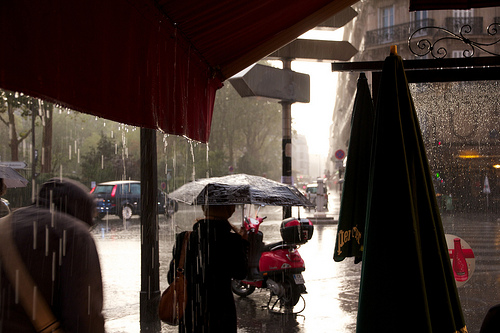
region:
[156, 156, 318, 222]
person holding an umbrella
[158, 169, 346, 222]
the umbrella is black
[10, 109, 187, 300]
it is raining in scene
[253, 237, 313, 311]
the motorcycle is red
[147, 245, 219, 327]
person carrying a purse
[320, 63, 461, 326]
the umbrellas are closed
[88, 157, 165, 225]
car's tail lights are on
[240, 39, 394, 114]
the signs are white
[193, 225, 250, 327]
person's jacket is black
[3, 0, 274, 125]
the awning is red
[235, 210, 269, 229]
The handle bars of the red scooter.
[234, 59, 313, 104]
The bottom sign on the post.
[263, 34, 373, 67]
The second sign on the post.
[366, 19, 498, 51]
The black balcony barriers above the business.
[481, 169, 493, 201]
The closed white umbrella in front of the door to the business across the street.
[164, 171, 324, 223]
The umbrella the lady is holding.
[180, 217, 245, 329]
The black coat the lady is wearing.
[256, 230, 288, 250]
The black seat of the scooter.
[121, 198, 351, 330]
The wet sidewalk in front of the lady.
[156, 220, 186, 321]
The brown purse the lady is holding under the umbrella.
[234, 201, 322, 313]
The red scooter parked under the street sign.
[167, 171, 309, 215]
The black umbrella the person is holding.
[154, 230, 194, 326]
The brown purse the person is holding.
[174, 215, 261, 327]
The black jacket the person under the umbrella is wearing.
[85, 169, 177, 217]
The small black vehicle in the street.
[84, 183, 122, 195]
The brake lights of the small black vehicle.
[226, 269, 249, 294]
The front wheel of the scooter.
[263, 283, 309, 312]
The back wheel of the scooter.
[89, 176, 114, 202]
The back window on the small black vehicle.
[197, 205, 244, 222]
The hat the person under the black umbrella is wearing.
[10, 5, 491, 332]
People standing in the rain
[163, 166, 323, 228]
A woman holding an umbrella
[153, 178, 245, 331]
A woman holding a purse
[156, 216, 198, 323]
A purse on a woman's shoulder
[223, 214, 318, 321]
A motorcycle on the sidewalk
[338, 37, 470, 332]
Umbrella's in the rain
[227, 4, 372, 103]
Arrow shaped signs on a pole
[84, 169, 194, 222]
A car in the street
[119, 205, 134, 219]
A tire on a car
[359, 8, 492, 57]
A balcony on a building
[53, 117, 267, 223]
It is raining outside.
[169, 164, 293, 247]
A person carrying an umbrella.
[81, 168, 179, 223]
Car driving down the street.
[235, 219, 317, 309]
A red motorbike on the corner.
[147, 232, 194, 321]
A person carrying a purse.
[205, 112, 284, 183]
Green trees by the street.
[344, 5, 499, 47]
A building with balconies.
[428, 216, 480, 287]
A sign on the window.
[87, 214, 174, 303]
The ground is wet.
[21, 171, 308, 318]
People walking in the rain.